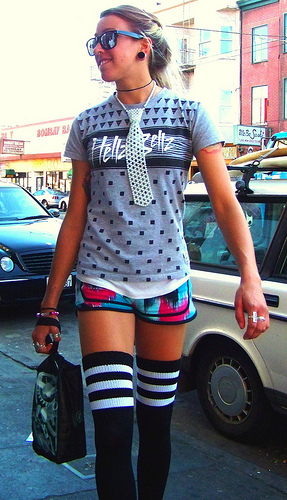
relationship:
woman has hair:
[31, 4, 273, 496] [99, 5, 181, 90]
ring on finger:
[246, 313, 257, 325] [243, 311, 258, 338]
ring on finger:
[38, 344, 46, 349] [39, 339, 56, 353]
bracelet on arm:
[38, 311, 61, 314] [38, 125, 89, 309]